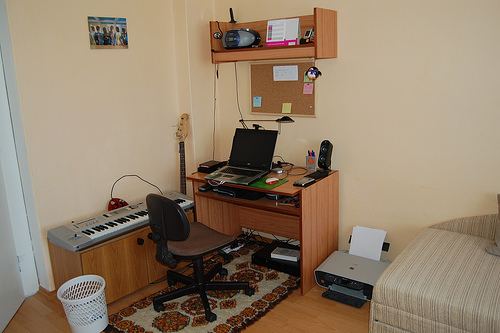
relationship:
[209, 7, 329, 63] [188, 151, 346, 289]
shelf above desk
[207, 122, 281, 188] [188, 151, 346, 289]
laptop on desk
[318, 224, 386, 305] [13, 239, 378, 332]
printer on floor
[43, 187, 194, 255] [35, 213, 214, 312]
keyboard on cabinet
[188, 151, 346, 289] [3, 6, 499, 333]
desk in room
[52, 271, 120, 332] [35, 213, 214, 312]
trash can by cabinet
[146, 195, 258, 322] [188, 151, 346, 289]
office chair by desk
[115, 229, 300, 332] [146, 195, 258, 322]
rug under office chair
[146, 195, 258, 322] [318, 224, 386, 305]
office chair by printer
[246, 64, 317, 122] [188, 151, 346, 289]
corkboard above desk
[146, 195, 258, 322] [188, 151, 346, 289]
office chair at a desk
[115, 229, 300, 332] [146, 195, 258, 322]
rug under a office chair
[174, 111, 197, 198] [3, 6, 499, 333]
guitar in room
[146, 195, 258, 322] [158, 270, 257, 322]
office chair on wheels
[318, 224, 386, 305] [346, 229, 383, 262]
printer with paper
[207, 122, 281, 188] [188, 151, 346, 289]
laptop on a desk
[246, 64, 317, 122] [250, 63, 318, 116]
corkboard with notes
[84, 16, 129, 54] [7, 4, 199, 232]
poster hung on wall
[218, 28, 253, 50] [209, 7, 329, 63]
boombox on shelf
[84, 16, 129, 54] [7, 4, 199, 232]
poster on wall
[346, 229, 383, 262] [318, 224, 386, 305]
paper in printer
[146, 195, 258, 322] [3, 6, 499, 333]
office chair in room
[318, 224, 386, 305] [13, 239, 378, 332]
printer sitting on floor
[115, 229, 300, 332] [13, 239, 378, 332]
rug on floor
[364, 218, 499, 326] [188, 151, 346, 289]
couch next to desk